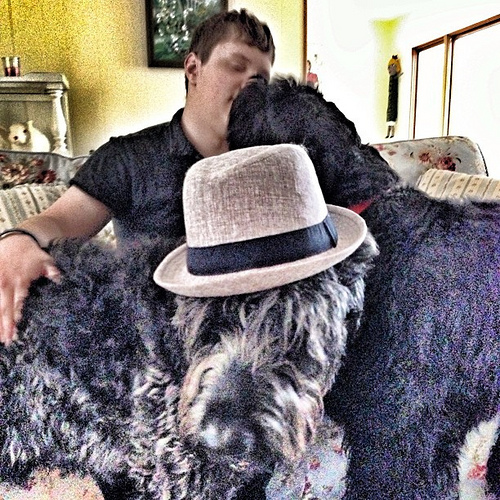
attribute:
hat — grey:
[142, 132, 372, 305]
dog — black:
[228, 77, 497, 498]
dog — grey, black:
[5, 220, 378, 498]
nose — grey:
[188, 406, 255, 454]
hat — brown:
[209, 147, 312, 281]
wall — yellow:
[0, 0, 305, 157]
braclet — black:
[3, 223, 38, 243]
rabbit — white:
[5, 106, 80, 163]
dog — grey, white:
[23, 251, 358, 453]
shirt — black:
[67, 103, 204, 248]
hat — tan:
[152, 142, 377, 297]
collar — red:
[339, 178, 409, 219]